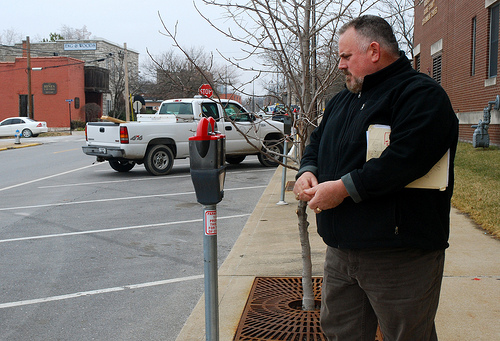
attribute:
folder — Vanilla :
[351, 115, 469, 197]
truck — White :
[76, 93, 295, 180]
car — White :
[0, 116, 50, 137]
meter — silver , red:
[182, 96, 243, 339]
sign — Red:
[131, 98, 142, 113]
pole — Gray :
[171, 102, 261, 339]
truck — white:
[81, 97, 285, 173]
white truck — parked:
[91, 84, 281, 158]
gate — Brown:
[228, 270, 411, 340]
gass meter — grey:
[187, 114, 230, 339]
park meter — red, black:
[181, 116, 237, 204]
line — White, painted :
[0, 273, 207, 310]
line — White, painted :
[0, 210, 250, 246]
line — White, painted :
[0, 182, 268, 213]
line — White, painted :
[16, 165, 278, 192]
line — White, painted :
[0, 159, 107, 194]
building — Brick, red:
[2, 44, 96, 132]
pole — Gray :
[281, 132, 288, 200]